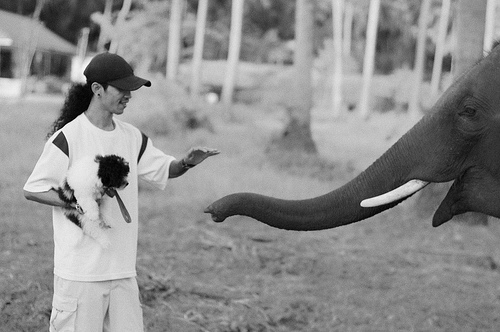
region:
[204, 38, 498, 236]
Gray elephant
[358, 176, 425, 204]
Elephant horn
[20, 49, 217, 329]
Female petting the elephant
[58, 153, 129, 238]
Doll held by the female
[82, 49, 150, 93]
Hat worn by the female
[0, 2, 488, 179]
Several trees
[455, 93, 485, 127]
Left eye of the elephant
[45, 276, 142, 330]
Cargo pants worn by the female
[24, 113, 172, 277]
White shirt worn by the female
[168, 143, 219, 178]
Left hand of the female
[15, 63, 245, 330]
A person in a yard.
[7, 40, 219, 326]
Person holding a dog.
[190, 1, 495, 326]
An elephant in a zoo.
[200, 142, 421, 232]
The trunk of an elephant.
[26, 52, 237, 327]
A man holding a dog.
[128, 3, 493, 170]
Trees behind the elephant.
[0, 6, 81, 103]
A building in the distance.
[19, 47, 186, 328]
Man in a black hat.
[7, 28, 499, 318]
Man looking at an elephant.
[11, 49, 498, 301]
Man getting ready to touch an elephant's trunk.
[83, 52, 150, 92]
the man is wearing a cap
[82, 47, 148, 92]
the cap is black in color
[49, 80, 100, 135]
the man has long hair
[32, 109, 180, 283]
the man is wearing a short sleeve shirt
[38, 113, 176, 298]
the shirt is white in color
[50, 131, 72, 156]
a stripe is on the shoulder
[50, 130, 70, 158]
the stripe is black in color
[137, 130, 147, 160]
the stripe is black in color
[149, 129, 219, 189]
the man has his arm raise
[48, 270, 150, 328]
the pants are white in color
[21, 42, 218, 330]
a person wearing a cap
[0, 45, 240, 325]
a person wearing a t shirt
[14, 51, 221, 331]
person has long hair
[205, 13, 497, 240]
an elephant with it's nose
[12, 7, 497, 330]
trainer and the elephant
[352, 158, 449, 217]
trunk of an elephant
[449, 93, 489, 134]
eye of an elephant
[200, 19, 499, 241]
head of an elephant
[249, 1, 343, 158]
tree stem in the background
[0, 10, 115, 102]
a cabin house in the background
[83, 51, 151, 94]
The black hat on a man.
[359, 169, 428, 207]
A white ivory tusk.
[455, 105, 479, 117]
Eye of an elephant.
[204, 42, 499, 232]
A dark grey elephant.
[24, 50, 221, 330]
A long black haired man with a black hat on.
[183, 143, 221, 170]
A man's left hand.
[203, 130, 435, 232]
Long dark grey trunk of an elephant.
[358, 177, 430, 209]
A large white ivory tusk.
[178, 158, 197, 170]
A dark watch band around a man's left wrist.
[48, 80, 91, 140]
Black curly hair coming out the back of a man's hat.